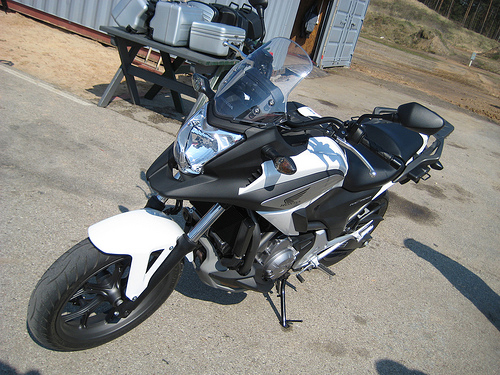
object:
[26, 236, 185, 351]
wheel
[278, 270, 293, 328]
kickstand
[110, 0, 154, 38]
container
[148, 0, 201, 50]
container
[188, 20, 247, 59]
container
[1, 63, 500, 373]
road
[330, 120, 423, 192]
seat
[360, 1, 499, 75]
grass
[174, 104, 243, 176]
headlight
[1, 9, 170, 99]
dirt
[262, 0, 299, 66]
door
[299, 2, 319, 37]
clothes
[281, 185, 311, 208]
logo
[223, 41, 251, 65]
brake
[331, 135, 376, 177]
brake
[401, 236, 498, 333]
shadow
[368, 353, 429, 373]
shadow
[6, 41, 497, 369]
pavement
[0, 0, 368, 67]
storage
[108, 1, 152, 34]
silver container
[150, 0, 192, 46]
silver container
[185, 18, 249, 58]
silver container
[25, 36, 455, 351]
bike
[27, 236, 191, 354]
bike tire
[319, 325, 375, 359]
oil spots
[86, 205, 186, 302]
cap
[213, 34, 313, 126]
windshield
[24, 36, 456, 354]
motorcycle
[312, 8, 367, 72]
container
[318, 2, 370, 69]
door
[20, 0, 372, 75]
metal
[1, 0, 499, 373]
ground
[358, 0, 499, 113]
dirt mound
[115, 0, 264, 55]
bags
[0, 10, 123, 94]
soil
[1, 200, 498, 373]
shadows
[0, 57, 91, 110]
line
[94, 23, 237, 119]
picnic table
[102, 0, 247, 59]
boxes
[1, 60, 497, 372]
paving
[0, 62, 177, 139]
edge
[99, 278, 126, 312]
wheel cap